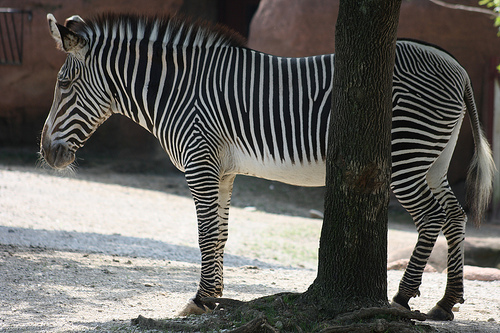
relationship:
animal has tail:
[36, 13, 499, 322] [429, 66, 490, 207]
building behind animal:
[55, 3, 484, 137] [36, 13, 499, 322]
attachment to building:
[0, 4, 23, 59] [2, 9, 479, 138]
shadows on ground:
[11, 230, 167, 310] [19, 182, 206, 329]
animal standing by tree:
[36, 13, 499, 322] [285, 0, 437, 326]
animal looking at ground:
[36, 13, 499, 322] [8, 186, 175, 314]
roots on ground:
[143, 300, 449, 330] [13, 193, 135, 330]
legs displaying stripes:
[174, 141, 227, 316] [192, 169, 217, 231]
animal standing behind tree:
[36, 13, 499, 322] [285, 0, 437, 326]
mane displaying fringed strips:
[58, 15, 243, 54] [73, 16, 228, 42]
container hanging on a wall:
[12, 8, 36, 59] [20, 17, 485, 169]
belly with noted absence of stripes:
[234, 167, 333, 187] [50, 28, 450, 158]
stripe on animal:
[133, 39, 149, 119] [36, 5, 485, 322]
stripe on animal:
[109, 34, 121, 116] [36, 5, 485, 322]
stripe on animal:
[182, 129, 205, 149] [36, 5, 485, 322]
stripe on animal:
[390, 102, 444, 123] [36, 5, 485, 322]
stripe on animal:
[401, 185, 431, 205] [36, 5, 485, 322]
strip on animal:
[183, 150, 203, 169] [36, 5, 485, 322]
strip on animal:
[300, 56, 311, 162] [36, 5, 485, 322]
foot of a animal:
[424, 303, 455, 320] [36, 13, 499, 322]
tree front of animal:
[227, 2, 421, 332] [36, 13, 499, 322]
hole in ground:
[453, 236, 484, 268] [391, 216, 482, 304]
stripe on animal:
[260, 52, 274, 156] [36, 5, 485, 322]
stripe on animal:
[249, 48, 261, 156] [36, 5, 485, 322]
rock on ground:
[99, 264, 119, 278] [35, 242, 169, 309]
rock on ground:
[144, 283, 153, 288] [102, 254, 185, 310]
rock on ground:
[112, 259, 132, 264] [62, 225, 169, 305]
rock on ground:
[112, 259, 132, 264] [24, 194, 178, 315]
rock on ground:
[106, 252, 131, 268] [46, 221, 171, 304]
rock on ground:
[53, 257, 76, 271] [19, 201, 175, 317]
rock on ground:
[262, 259, 282, 273] [230, 214, 304, 288]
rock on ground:
[264, 277, 276, 286] [233, 244, 298, 291]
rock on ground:
[139, 277, 155, 291] [50, 217, 200, 313]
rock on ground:
[484, 310, 498, 331] [459, 304, 499, 325]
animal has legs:
[36, 13, 499, 322] [179, 164, 235, 322]